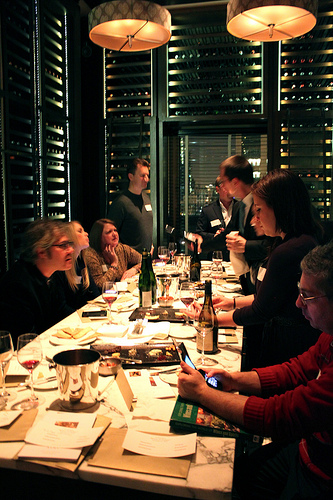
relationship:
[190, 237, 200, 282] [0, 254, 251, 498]
bottle on table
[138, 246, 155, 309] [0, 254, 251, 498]
bottle on table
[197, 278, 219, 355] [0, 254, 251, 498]
bottle on table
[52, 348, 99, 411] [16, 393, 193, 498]
bucket on table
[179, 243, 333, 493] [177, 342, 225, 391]
man observing ir phone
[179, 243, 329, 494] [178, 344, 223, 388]
man checking phone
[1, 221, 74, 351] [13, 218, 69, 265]
man with hair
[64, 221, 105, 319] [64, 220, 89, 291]
woman with hair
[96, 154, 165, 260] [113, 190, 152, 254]
man in sweater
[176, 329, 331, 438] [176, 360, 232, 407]
arms and hands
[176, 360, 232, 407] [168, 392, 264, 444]
hands are on a book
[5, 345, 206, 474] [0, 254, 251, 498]
papers are on table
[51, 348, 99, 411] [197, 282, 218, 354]
bucket for bottle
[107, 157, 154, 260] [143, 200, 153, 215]
man wearing a name tag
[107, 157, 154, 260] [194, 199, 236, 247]
man wearing blazer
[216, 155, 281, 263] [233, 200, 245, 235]
man wearing tie